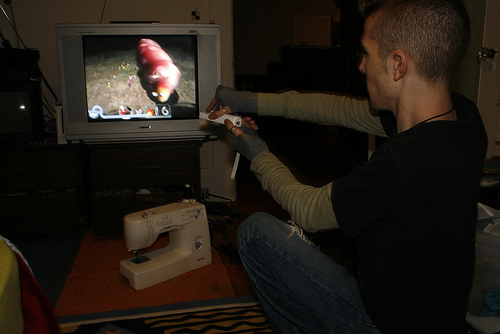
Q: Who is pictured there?
A: Young man.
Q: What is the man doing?
A: Playing game.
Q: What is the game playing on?
A: TV.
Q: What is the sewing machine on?
A: Blanket.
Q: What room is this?
A: Living room.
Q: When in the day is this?
A: Evening.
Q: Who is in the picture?
A: A man.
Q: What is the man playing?
A: Wii.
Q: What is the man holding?
A: Wii.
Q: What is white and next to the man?
A: Sewing machine.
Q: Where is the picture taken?
A: Living room.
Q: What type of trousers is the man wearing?
A: Jeans.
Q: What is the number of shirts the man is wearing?
A: Two.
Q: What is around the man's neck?
A: Necklace.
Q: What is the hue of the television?
A: White.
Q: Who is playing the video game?
A: The man.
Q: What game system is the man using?
A: Nintendo wii.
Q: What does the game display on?
A: A TV.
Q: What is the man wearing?
A: Jeans and a long sleeved shirt.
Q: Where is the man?
A: Sitting in front of the TV.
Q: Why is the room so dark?
A: The lights are turned off.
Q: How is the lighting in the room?
A: Dark.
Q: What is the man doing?
A: Playing nintendo wii.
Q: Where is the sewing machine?
A: On the table.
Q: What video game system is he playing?
A: Nintendo wii.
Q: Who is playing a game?
A: The man.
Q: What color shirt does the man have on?
A: Black.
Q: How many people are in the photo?
A: One.